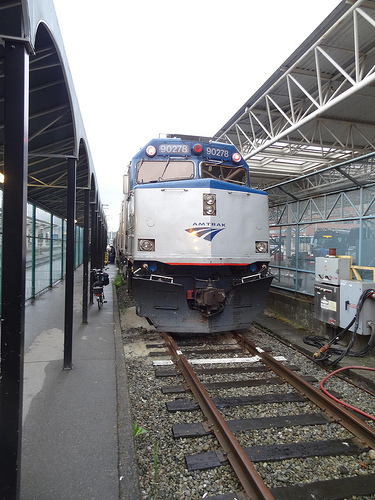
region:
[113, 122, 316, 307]
front of the train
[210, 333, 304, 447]
track under the train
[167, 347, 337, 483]
train track on the ground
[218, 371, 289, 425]
rocks on the track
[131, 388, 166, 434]
rocks next to the track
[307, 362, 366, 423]
orange hose on ground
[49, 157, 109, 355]
pole next to train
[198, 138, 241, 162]
number on the train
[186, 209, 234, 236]
word on the train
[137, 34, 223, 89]
sky above the train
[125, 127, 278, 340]
train on the track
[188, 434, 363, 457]
cross tie on track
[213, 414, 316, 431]
cross tie on track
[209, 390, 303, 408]
cross tie on track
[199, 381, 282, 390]
cross tie on track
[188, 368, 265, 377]
cross tie on track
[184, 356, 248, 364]
cross tie on track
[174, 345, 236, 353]
cross tie on track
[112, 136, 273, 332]
a blue and silver train engine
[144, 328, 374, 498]
a set of train tracks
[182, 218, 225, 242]
AMTRAK painted logo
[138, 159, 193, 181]
a train passenger window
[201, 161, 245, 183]
a train passenger window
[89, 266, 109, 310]
a parked bicycle on platform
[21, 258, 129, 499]
a passenger boarding platform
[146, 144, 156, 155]
a train front headlight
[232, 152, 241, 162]
a train front headlight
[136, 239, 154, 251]
a train front headlight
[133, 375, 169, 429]
rocks on the ground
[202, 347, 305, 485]
brown tracks under train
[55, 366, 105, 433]
cement next to tracks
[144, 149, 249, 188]
windows on the train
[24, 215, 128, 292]
poles next to train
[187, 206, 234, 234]
word on front of train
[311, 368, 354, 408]
red hose on the ground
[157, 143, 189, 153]
white number print on a train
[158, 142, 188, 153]
number print on a train reading 90278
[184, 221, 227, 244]
blue amtrack logo print on a train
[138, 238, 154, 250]
round white light on a train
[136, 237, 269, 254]
two white lights on the front of a train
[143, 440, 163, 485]
green plant on a train tack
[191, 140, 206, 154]
round red light on a train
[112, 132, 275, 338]
Amtrak train on a track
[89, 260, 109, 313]
bicycle parked on train platform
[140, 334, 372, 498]
train tracks with rocky gravel surrounding it